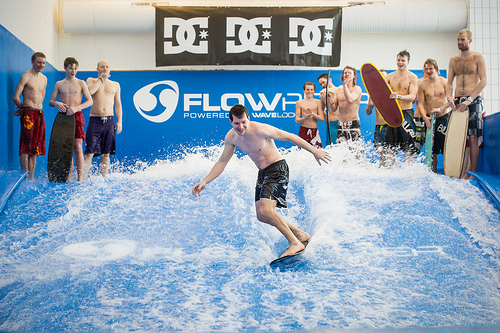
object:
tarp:
[0, 173, 500, 332]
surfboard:
[444, 104, 471, 177]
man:
[191, 104, 332, 259]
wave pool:
[0, 137, 500, 332]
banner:
[154, 4, 342, 67]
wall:
[59, 1, 468, 159]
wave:
[0, 138, 500, 332]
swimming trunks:
[335, 120, 361, 143]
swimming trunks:
[453, 95, 486, 148]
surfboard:
[46, 107, 77, 184]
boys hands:
[66, 105, 81, 117]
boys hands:
[386, 91, 401, 101]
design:
[130, 79, 181, 124]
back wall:
[56, 68, 461, 172]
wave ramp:
[0, 179, 500, 332]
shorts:
[85, 115, 116, 157]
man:
[47, 56, 96, 186]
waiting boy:
[13, 52, 49, 181]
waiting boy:
[446, 25, 489, 180]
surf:
[192, 101, 334, 265]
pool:
[0, 139, 500, 332]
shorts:
[253, 158, 293, 208]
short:
[17, 107, 47, 157]